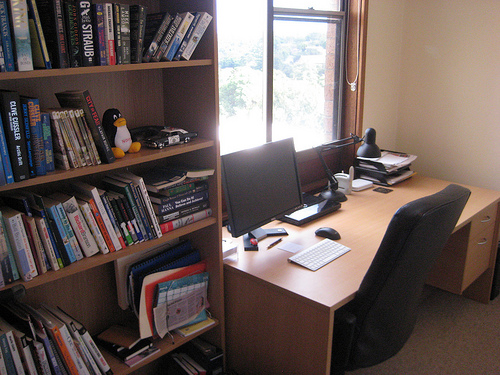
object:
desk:
[217, 160, 499, 374]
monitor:
[220, 138, 309, 240]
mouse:
[314, 226, 344, 240]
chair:
[330, 182, 471, 371]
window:
[215, 0, 366, 161]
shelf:
[0, 0, 227, 375]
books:
[0, 0, 216, 72]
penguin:
[102, 106, 142, 158]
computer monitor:
[209, 136, 305, 238]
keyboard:
[288, 237, 353, 272]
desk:
[222, 159, 499, 375]